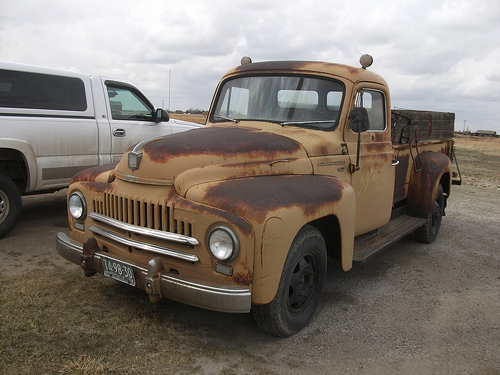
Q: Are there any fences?
A: No, there are no fences.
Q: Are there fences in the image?
A: No, there are no fences.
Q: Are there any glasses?
A: No, there are no glasses.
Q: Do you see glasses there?
A: No, there are no glasses.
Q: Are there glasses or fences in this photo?
A: No, there are no glasses or fences.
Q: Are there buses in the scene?
A: No, there are no buses.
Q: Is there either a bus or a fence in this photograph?
A: No, there are no buses or fences.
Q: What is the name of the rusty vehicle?
A: The vehicle is a car.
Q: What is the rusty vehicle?
A: The vehicle is a car.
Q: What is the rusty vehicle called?
A: The vehicle is a car.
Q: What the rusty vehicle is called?
A: The vehicle is a car.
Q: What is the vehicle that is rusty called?
A: The vehicle is a car.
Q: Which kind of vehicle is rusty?
A: The vehicle is a car.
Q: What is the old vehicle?
A: The vehicle is a car.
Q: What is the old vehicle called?
A: The vehicle is a car.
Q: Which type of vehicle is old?
A: The vehicle is a car.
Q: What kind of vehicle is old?
A: The vehicle is a car.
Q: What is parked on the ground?
A: The car is parked on the ground.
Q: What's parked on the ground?
A: The car is parked on the ground.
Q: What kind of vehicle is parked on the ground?
A: The vehicle is a car.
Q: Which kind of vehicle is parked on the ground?
A: The vehicle is a car.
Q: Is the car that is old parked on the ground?
A: Yes, the car is parked on the ground.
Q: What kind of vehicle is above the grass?
A: The vehicle is a car.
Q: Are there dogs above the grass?
A: No, there is a car above the grass.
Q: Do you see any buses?
A: No, there are no buses.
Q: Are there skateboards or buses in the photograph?
A: No, there are no buses or skateboards.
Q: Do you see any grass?
A: Yes, there is grass.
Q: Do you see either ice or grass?
A: Yes, there is grass.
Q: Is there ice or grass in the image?
A: Yes, there is grass.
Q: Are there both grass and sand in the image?
A: No, there is grass but no sand.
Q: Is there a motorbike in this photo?
A: No, there are no motorcycles.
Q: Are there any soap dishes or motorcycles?
A: No, there are no motorcycles or soap dishes.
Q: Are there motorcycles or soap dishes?
A: No, there are no motorcycles or soap dishes.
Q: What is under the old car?
A: The grass is under the car.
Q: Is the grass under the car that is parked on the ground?
A: Yes, the grass is under the car.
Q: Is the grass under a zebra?
A: No, the grass is under the car.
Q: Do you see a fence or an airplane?
A: No, there are no fences or airplanes.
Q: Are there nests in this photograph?
A: No, there are no nests.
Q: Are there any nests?
A: No, there are no nests.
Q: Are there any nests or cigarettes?
A: No, there are no nests or cigarettes.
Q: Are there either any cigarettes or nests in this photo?
A: No, there are no nests or cigarettes.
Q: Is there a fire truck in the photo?
A: No, there are no fire trucks.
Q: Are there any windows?
A: Yes, there is a window.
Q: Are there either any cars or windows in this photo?
A: Yes, there is a window.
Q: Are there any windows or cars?
A: Yes, there is a window.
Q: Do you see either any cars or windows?
A: Yes, there is a window.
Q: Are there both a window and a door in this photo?
A: Yes, there are both a window and a door.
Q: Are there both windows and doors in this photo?
A: Yes, there are both a window and doors.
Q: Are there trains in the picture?
A: No, there are no trains.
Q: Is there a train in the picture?
A: No, there are no trains.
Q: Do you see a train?
A: No, there are no trains.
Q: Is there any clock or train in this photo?
A: No, there are no trains or clocks.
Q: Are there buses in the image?
A: No, there are no buses.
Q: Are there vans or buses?
A: No, there are no buses or vans.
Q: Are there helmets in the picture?
A: No, there are no helmets.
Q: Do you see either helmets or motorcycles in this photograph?
A: No, there are no helmets or motorcycles.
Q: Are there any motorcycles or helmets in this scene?
A: No, there are no helmets or motorcycles.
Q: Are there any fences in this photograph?
A: No, there are no fences.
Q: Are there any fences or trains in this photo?
A: No, there are no fences or trains.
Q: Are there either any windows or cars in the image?
A: Yes, there is a window.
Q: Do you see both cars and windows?
A: Yes, there are both a window and a car.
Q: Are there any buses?
A: No, there are no buses.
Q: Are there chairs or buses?
A: No, there are no buses or chairs.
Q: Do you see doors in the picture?
A: Yes, there is a door.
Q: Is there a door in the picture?
A: Yes, there is a door.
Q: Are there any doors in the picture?
A: Yes, there is a door.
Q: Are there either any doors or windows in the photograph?
A: Yes, there is a door.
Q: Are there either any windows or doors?
A: Yes, there is a door.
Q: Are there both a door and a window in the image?
A: Yes, there are both a door and a window.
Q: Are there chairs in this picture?
A: No, there are no chairs.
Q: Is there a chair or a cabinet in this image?
A: No, there are no chairs or cabinets.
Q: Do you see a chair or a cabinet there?
A: No, there are no chairs or cabinets.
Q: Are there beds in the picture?
A: Yes, there is a bed.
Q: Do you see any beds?
A: Yes, there is a bed.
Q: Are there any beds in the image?
A: Yes, there is a bed.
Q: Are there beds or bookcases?
A: Yes, there is a bed.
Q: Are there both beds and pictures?
A: No, there is a bed but no pictures.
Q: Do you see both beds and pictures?
A: No, there is a bed but no pictures.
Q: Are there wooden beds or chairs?
A: Yes, there is a wood bed.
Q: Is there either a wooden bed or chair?
A: Yes, there is a wood bed.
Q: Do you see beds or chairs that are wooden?
A: Yes, the bed is wooden.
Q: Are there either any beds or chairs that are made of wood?
A: Yes, the bed is made of wood.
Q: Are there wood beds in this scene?
A: Yes, there is a wood bed.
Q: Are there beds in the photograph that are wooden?
A: Yes, there is a bed that is wooden.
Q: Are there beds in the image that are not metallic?
A: Yes, there is a wooden bed.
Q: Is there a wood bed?
A: Yes, there is a bed that is made of wood.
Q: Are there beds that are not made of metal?
A: Yes, there is a bed that is made of wood.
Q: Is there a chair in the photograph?
A: No, there are no chairs.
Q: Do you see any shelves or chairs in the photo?
A: No, there are no chairs or shelves.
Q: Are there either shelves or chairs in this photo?
A: No, there are no chairs or shelves.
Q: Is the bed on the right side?
A: Yes, the bed is on the right of the image.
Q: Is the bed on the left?
A: No, the bed is on the right of the image.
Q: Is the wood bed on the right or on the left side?
A: The bed is on the right of the image.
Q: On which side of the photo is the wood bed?
A: The bed is on the right of the image.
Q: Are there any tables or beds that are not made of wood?
A: No, there is a bed but it is made of wood.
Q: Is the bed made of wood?
A: Yes, the bed is made of wood.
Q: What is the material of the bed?
A: The bed is made of wood.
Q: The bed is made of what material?
A: The bed is made of wood.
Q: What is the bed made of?
A: The bed is made of wood.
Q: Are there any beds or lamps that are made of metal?
A: No, there is a bed but it is made of wood.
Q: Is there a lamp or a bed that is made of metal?
A: No, there is a bed but it is made of wood.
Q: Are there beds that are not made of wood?
A: No, there is a bed but it is made of wood.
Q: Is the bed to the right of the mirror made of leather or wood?
A: The bed is made of wood.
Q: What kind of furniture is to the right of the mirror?
A: The piece of furniture is a bed.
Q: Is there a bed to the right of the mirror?
A: Yes, there is a bed to the right of the mirror.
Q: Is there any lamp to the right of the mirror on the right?
A: No, there is a bed to the right of the mirror.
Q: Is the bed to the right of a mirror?
A: Yes, the bed is to the right of a mirror.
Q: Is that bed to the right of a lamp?
A: No, the bed is to the right of a mirror.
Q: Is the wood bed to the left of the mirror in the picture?
A: No, the bed is to the right of the mirror.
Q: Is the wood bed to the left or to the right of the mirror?
A: The bed is to the right of the mirror.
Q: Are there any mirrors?
A: Yes, there is a mirror.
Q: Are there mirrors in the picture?
A: Yes, there is a mirror.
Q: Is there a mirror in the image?
A: Yes, there is a mirror.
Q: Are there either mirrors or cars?
A: Yes, there is a mirror.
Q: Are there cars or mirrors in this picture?
A: Yes, there is a mirror.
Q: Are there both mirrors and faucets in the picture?
A: No, there is a mirror but no faucets.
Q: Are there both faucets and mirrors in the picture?
A: No, there is a mirror but no faucets.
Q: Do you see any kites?
A: No, there are no kites.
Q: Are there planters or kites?
A: No, there are no kites or planters.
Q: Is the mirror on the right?
A: Yes, the mirror is on the right of the image.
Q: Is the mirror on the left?
A: No, the mirror is on the right of the image.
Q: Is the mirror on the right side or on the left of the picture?
A: The mirror is on the right of the image.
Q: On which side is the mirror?
A: The mirror is on the right of the image.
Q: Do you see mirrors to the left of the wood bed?
A: Yes, there is a mirror to the left of the bed.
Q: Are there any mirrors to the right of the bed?
A: No, the mirror is to the left of the bed.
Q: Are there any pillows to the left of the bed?
A: No, there is a mirror to the left of the bed.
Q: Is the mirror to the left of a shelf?
A: No, the mirror is to the left of the bed.